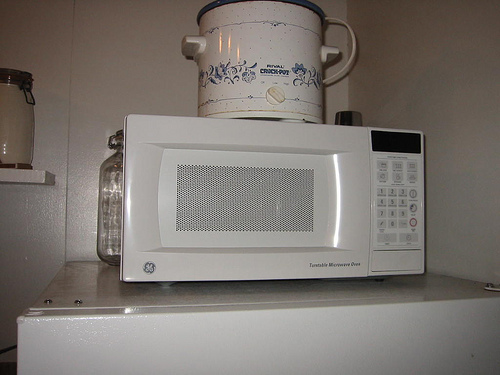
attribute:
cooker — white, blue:
[186, 2, 359, 128]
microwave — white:
[119, 113, 434, 279]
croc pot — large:
[194, 12, 326, 111]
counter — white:
[22, 291, 483, 361]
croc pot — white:
[178, 5, 335, 117]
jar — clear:
[66, 127, 142, 264]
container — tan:
[4, 63, 36, 164]